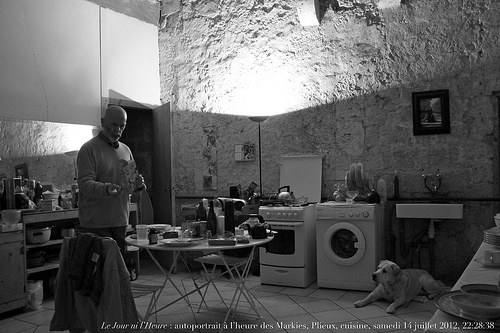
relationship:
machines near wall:
[257, 191, 402, 302] [157, 3, 498, 303]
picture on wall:
[407, 85, 447, 135] [225, 27, 488, 176]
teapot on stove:
[277, 187, 293, 204] [251, 190, 320, 292]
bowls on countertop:
[432, 280, 499, 326] [430, 219, 497, 331]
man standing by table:
[73, 107, 146, 248] [129, 215, 275, 331]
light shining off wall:
[216, 71, 295, 115] [256, 77, 316, 124]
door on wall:
[105, 88, 177, 274] [36, 22, 173, 132]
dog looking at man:
[346, 260, 453, 318] [76, 106, 147, 263]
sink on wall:
[397, 184, 474, 232] [157, 3, 498, 303]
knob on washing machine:
[362, 210, 370, 220] [314, 197, 380, 290]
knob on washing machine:
[355, 210, 360, 215] [314, 197, 380, 290]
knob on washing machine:
[347, 212, 356, 217] [314, 197, 380, 290]